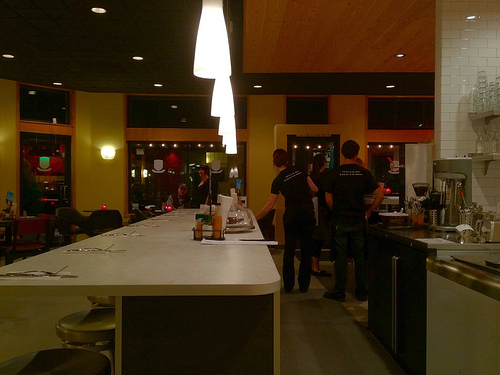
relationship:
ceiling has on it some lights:
[15, 7, 426, 89] [85, 4, 187, 93]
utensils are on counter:
[17, 209, 193, 278] [0, 208, 284, 296]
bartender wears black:
[315, 138, 386, 299] [327, 169, 375, 291]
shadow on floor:
[292, 299, 369, 324] [276, 242, 398, 374]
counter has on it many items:
[0, 208, 284, 296] [193, 183, 256, 254]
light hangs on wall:
[97, 143, 122, 164] [75, 91, 126, 216]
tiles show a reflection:
[445, 23, 485, 155] [457, 8, 483, 62]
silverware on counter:
[10, 256, 79, 288] [0, 208, 284, 296]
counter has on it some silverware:
[0, 208, 284, 296] [10, 256, 79, 288]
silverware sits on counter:
[10, 256, 79, 288] [16, 195, 284, 295]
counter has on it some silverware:
[16, 195, 284, 295] [10, 256, 79, 288]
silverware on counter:
[10, 256, 79, 288] [16, 195, 284, 295]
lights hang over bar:
[85, 4, 187, 93] [25, 195, 286, 365]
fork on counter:
[20, 260, 74, 276] [0, 208, 284, 296]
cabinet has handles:
[366, 234, 431, 364] [386, 253, 401, 356]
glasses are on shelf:
[468, 76, 499, 111] [469, 109, 499, 123]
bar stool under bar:
[57, 306, 118, 371] [25, 195, 286, 365]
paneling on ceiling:
[240, 5, 435, 72] [15, 7, 426, 89]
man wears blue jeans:
[315, 138, 386, 299] [332, 220, 369, 292]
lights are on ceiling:
[85, 4, 187, 93] [15, 7, 426, 89]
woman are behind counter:
[255, 148, 319, 293] [16, 195, 284, 295]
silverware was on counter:
[10, 256, 79, 288] [16, 195, 284, 295]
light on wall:
[97, 143, 122, 164] [75, 91, 126, 216]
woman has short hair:
[250, 143, 317, 294] [270, 145, 291, 170]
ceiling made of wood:
[15, 7, 426, 89] [246, 10, 310, 63]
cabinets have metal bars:
[366, 234, 431, 364] [386, 253, 401, 356]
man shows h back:
[315, 138, 386, 299] [330, 170, 377, 227]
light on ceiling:
[89, 3, 113, 18] [15, 7, 426, 89]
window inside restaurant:
[127, 132, 245, 212] [13, 34, 488, 357]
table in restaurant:
[4, 209, 62, 235] [13, 34, 488, 357]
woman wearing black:
[250, 143, 317, 294] [276, 172, 315, 221]